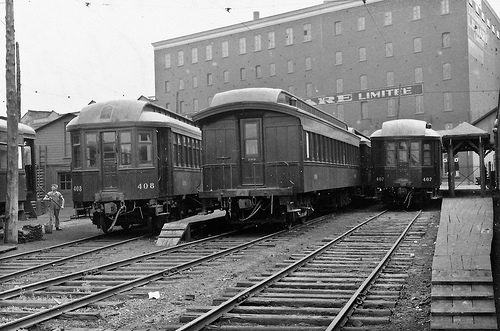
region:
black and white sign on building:
[282, 81, 432, 109]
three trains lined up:
[38, 92, 449, 254]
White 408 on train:
[134, 175, 160, 197]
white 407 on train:
[421, 172, 433, 186]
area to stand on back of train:
[196, 150, 305, 217]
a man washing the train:
[23, 164, 78, 241]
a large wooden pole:
[0, 2, 32, 247]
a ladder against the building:
[35, 141, 59, 226]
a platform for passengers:
[435, 171, 497, 286]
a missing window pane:
[299, 25, 314, 45]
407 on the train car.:
[418, 170, 443, 192]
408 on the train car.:
[122, 166, 163, 196]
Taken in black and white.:
[0, 12, 498, 328]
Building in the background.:
[151, 0, 498, 131]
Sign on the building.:
[290, 78, 428, 102]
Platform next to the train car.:
[438, 161, 497, 316]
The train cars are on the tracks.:
[81, 200, 426, 321]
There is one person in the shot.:
[36, 180, 74, 230]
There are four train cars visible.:
[1, 75, 443, 233]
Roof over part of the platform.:
[439, 113, 491, 198]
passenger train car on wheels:
[92, 89, 156, 237]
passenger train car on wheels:
[193, 90, 324, 228]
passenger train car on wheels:
[377, 105, 440, 200]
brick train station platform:
[438, 176, 491, 284]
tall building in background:
[157, 30, 487, 174]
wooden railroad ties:
[237, 273, 322, 322]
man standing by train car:
[44, 167, 79, 249]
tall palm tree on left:
[0, 12, 31, 253]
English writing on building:
[352, 77, 429, 114]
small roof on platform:
[452, 120, 499, 159]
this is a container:
[202, 96, 309, 216]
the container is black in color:
[262, 131, 296, 189]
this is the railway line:
[308, 241, 397, 318]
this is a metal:
[359, 229, 399, 288]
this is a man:
[43, 188, 68, 226]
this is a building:
[218, 20, 457, 75]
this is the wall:
[330, 25, 377, 47]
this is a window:
[356, 15, 367, 27]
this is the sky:
[90, 25, 124, 69]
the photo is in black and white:
[50, 11, 414, 206]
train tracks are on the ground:
[55, 212, 317, 329]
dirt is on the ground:
[115, 256, 210, 305]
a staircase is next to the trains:
[421, 205, 472, 307]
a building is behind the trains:
[145, 55, 432, 85]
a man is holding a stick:
[30, 178, 125, 251]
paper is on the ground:
[123, 291, 227, 328]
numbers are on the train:
[134, 175, 194, 210]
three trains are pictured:
[45, 80, 431, 309]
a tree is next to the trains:
[0, 15, 69, 252]